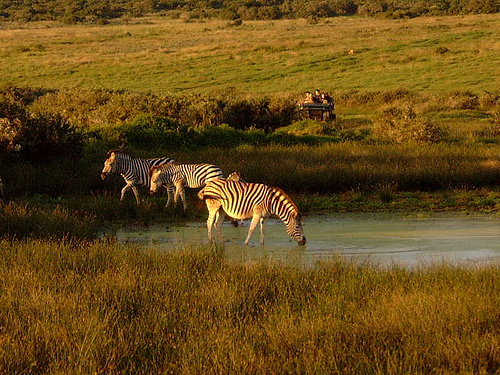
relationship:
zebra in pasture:
[196, 178, 307, 253] [1, 207, 498, 373]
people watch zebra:
[300, 89, 334, 106] [196, 178, 307, 253]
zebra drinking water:
[196, 178, 307, 253] [102, 214, 500, 290]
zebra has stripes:
[196, 178, 307, 253] [211, 179, 286, 218]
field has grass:
[4, 13, 500, 105] [6, 31, 497, 86]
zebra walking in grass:
[98, 151, 230, 207] [6, 31, 497, 86]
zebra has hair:
[196, 178, 307, 253] [275, 187, 301, 218]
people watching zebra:
[300, 89, 334, 106] [196, 178, 307, 253]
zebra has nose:
[196, 178, 307, 253] [296, 238, 307, 247]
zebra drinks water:
[196, 178, 307, 253] [102, 214, 500, 290]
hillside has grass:
[4, 13, 500, 105] [6, 31, 497, 86]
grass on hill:
[6, 31, 497, 86] [4, 13, 500, 105]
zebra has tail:
[196, 178, 307, 253] [197, 187, 221, 202]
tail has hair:
[197, 187, 221, 202] [207, 196, 223, 202]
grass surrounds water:
[6, 31, 497, 86] [102, 214, 500, 290]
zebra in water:
[98, 151, 230, 207] [102, 214, 500, 290]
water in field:
[102, 214, 500, 290] [4, 13, 500, 105]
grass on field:
[6, 31, 497, 86] [4, 13, 500, 105]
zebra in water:
[196, 178, 307, 253] [102, 214, 500, 290]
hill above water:
[6, 31, 497, 86] [102, 214, 500, 290]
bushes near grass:
[6, 113, 84, 166] [6, 31, 497, 86]